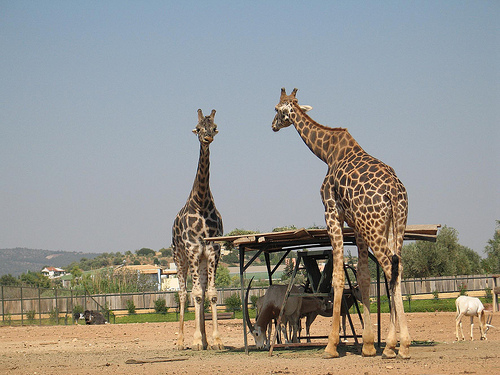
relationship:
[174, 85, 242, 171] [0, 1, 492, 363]
giraffe looking at camera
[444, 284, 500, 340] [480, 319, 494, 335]
goat has long horns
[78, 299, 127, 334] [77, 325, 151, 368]
black cow on ground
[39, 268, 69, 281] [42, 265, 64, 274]
white house has red roof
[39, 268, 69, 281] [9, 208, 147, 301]
white house in distance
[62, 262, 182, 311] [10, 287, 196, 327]
trees next to fence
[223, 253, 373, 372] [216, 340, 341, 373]
goats on dry grass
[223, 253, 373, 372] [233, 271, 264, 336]
animals have horn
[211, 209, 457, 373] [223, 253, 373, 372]
structure over animals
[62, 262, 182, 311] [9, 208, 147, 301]
trees in distance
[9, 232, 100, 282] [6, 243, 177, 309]
hills in distance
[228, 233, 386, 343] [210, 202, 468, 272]
antelopes in shade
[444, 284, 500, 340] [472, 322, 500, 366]
antelope looking for food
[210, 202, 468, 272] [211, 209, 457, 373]
boards on structure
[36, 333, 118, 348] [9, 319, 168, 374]
pebbles on ground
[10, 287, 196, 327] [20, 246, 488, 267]
fence along edge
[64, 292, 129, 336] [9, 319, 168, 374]
animal on ground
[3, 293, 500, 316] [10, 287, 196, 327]
grass along fence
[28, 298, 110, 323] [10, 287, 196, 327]
bush along fence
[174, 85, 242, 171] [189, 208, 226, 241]
giraffe has spots